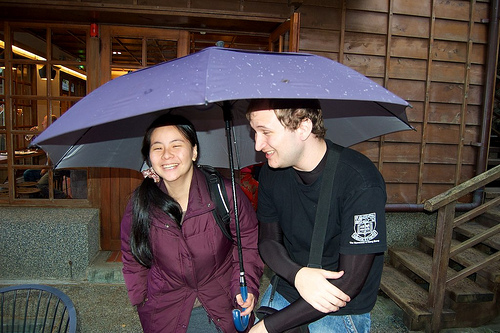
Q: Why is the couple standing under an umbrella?
A: Because it's raining.